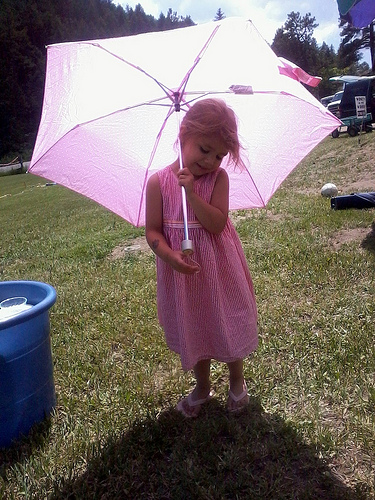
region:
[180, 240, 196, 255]
Rounded end of an umbrella.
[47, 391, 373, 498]
Shadow of the umbrella on the grass.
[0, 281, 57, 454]
A big plastic tub on the ground.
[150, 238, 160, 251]
A fake tattoo on a girls arm.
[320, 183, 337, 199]
Soccer ball lying in the grass.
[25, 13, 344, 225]
Pink umbrella that is opened up.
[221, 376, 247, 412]
The left pink flip flop of a little girl.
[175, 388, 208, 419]
The right pink flip flop of a girl.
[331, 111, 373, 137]
A green wagon with black wheels.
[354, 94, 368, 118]
A tall white sign with black letters on it.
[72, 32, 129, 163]
this is an umbrella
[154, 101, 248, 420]
this is a child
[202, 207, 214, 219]
the child has a light skin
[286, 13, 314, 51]
this is a tree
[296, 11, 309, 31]
the tree has green leaves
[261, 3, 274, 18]
this is the sky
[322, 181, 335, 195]
this is a ball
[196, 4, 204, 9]
the sky is blue in color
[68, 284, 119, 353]
this is a grass area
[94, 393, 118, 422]
the grass is green in color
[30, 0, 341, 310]
child with umbrella on a sunny day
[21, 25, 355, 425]
child standing on grass in a park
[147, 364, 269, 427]
feet in light-colored flip flops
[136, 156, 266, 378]
young girl wearing pink and white sun dress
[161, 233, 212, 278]
hands on loop at end of umbrella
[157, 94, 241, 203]
hand under face holding pole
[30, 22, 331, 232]
open pink umbrella behind girl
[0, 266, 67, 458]
large blue container with cup inside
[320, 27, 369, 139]
vehicles parked to the side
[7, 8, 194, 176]
thick wall of trees behind girl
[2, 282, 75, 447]
the bucket is blue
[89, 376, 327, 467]
the grass is green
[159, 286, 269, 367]
the dress is pink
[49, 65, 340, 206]
the umbrella is pink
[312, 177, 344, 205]
the ball is white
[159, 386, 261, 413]
the slippers are pink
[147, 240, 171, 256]
she has a tatoo on her hand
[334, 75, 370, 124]
the back door is open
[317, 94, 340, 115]
the cars are parked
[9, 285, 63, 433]
the bucket has liquid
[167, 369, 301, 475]
grass is green and brown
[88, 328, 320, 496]
grass is green and brown